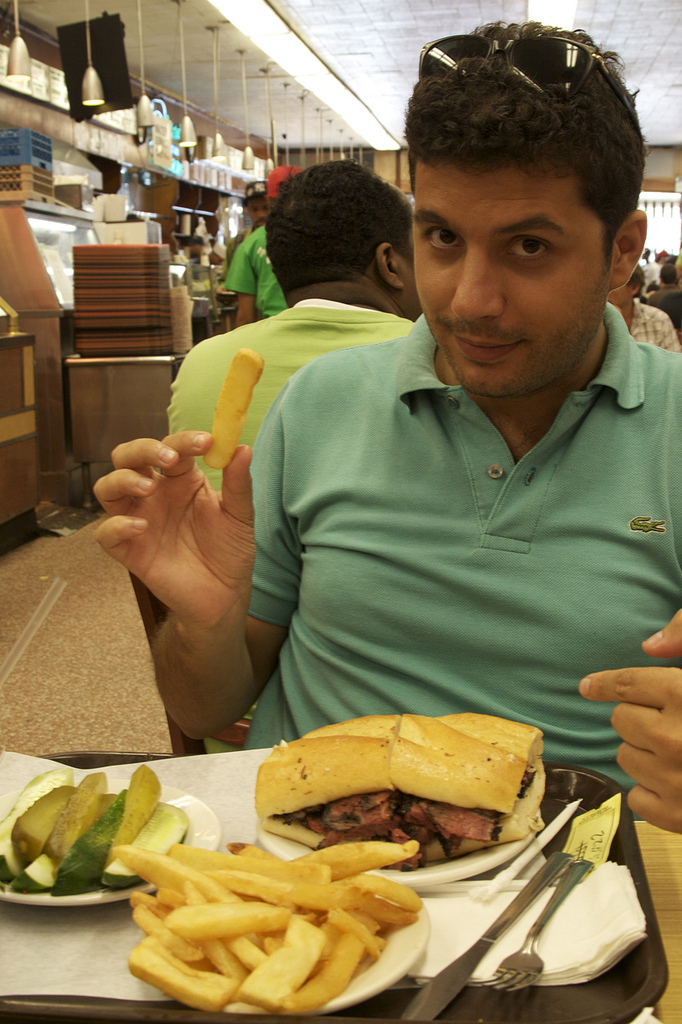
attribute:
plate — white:
[17, 755, 235, 932]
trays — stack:
[76, 239, 166, 364]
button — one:
[481, 447, 505, 486]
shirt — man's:
[265, 308, 674, 755]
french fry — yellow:
[198, 353, 269, 472]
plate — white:
[184, 789, 223, 847]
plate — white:
[419, 837, 535, 899]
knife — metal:
[407, 853, 571, 1020]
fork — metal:
[494, 858, 595, 1000]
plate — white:
[340, 908, 433, 1013]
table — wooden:
[634, 819, 660, 884]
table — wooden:
[636, 818, 660, 857]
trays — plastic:
[71, 240, 180, 356]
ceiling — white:
[230, 1, 393, 141]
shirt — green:
[259, 300, 647, 734]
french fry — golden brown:
[209, 344, 267, 470]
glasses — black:
[410, 25, 596, 89]